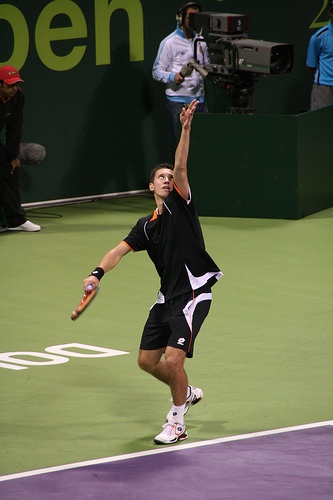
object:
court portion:
[0, 419, 332, 500]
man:
[81, 98, 223, 444]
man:
[150, 0, 211, 152]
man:
[0, 63, 42, 232]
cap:
[0, 64, 25, 86]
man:
[305, 5, 333, 115]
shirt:
[305, 19, 332, 88]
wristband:
[89, 266, 104, 280]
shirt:
[122, 175, 222, 303]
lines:
[170, 179, 187, 200]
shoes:
[153, 413, 187, 444]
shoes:
[6, 219, 39, 233]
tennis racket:
[68, 283, 99, 321]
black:
[1, 89, 28, 229]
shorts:
[140, 284, 211, 358]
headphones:
[174, 1, 202, 31]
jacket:
[150, 25, 210, 106]